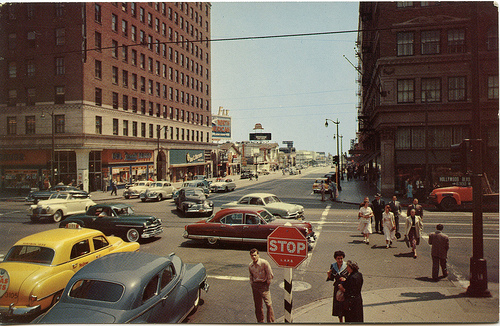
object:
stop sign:
[267, 226, 308, 269]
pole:
[284, 268, 293, 324]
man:
[249, 248, 275, 324]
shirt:
[248, 258, 273, 284]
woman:
[327, 250, 351, 322]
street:
[0, 162, 499, 325]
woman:
[338, 260, 364, 322]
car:
[27, 249, 209, 325]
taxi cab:
[3, 243, 69, 268]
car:
[182, 207, 317, 248]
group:
[357, 192, 425, 258]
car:
[59, 202, 164, 243]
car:
[220, 193, 305, 219]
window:
[398, 79, 415, 103]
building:
[358, 1, 500, 211]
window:
[421, 78, 441, 102]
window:
[448, 77, 467, 102]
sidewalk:
[278, 284, 496, 323]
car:
[173, 180, 212, 201]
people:
[407, 181, 414, 204]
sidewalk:
[333, 192, 430, 206]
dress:
[382, 211, 397, 241]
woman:
[382, 205, 397, 249]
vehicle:
[312, 178, 331, 194]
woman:
[357, 200, 373, 243]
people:
[404, 209, 424, 259]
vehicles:
[0, 222, 140, 323]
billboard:
[212, 115, 232, 138]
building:
[1, 1, 212, 192]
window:
[96, 116, 101, 134]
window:
[55, 87, 65, 105]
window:
[55, 57, 65, 74]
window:
[26, 116, 36, 135]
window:
[8, 117, 17, 135]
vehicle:
[175, 188, 214, 217]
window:
[186, 190, 202, 197]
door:
[243, 213, 270, 245]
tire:
[123, 228, 141, 242]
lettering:
[112, 152, 151, 161]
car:
[26, 190, 97, 223]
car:
[140, 181, 174, 202]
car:
[210, 178, 236, 193]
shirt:
[319, 183, 325, 192]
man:
[320, 180, 325, 201]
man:
[328, 179, 336, 198]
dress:
[359, 206, 373, 234]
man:
[428, 224, 449, 280]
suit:
[429, 231, 449, 279]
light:
[325, 122, 328, 127]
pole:
[337, 118, 341, 191]